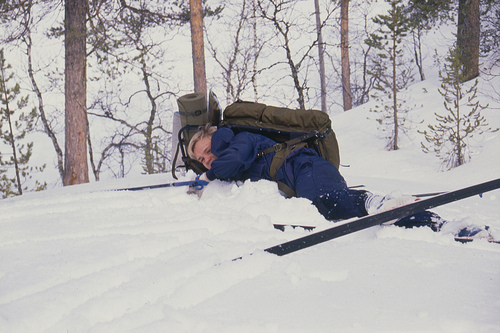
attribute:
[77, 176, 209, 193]
pole — ski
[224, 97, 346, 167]
backpack — green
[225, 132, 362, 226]
suit — blue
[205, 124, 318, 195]
jacket — blue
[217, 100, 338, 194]
backpack — olive colored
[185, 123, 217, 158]
hair — blonde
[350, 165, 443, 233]
boot — white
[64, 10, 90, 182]
trunk — pine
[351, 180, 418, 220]
ski boots — white colored 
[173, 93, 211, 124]
roll — brown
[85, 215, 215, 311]
snow — fluffy, white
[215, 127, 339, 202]
snowsuit — blue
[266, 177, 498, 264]
dark ski — dark colored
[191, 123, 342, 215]
jacket — blue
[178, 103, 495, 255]
skier —  down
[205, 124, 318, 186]
jacket — blue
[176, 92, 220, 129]
bedroll — green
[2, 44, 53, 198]
tree — pine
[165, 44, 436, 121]
tree — young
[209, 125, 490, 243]
suit — blue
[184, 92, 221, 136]
bedroll — brown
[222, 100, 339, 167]
backpack — olive colored, outdoor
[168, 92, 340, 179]
backpack — army green